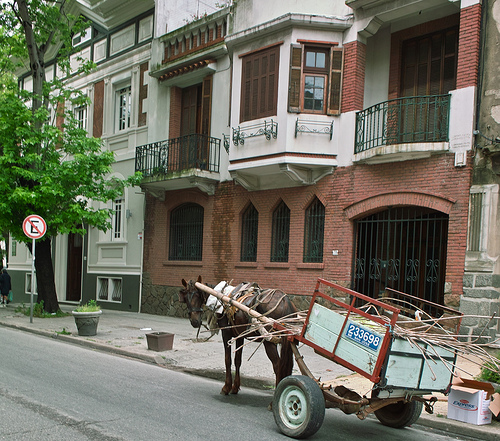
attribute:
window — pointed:
[300, 190, 330, 269]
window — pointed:
[267, 194, 295, 270]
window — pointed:
[233, 189, 263, 273]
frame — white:
[121, 190, 128, 245]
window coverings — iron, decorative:
[233, 192, 327, 264]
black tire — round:
[272, 373, 326, 439]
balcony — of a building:
[349, 79, 454, 152]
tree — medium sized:
[16, 28, 117, 318]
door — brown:
[56, 226, 88, 291]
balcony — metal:
[116, 128, 237, 191]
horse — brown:
[174, 270, 334, 424]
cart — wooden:
[296, 268, 492, 426]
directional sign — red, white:
[12, 213, 52, 245]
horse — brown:
[170, 273, 313, 400]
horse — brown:
[181, 270, 311, 388]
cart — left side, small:
[286, 277, 456, 428]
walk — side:
[102, 292, 130, 348]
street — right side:
[7, 315, 92, 440]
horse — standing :
[170, 274, 357, 405]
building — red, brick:
[140, 102, 459, 296]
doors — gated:
[355, 200, 444, 296]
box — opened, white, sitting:
[445, 377, 493, 437]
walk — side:
[431, 402, 491, 440]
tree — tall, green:
[15, 10, 122, 335]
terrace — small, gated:
[138, 69, 209, 213]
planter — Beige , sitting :
[75, 292, 104, 340]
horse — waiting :
[176, 280, 317, 400]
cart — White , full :
[294, 284, 404, 440]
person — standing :
[3, 260, 17, 305]